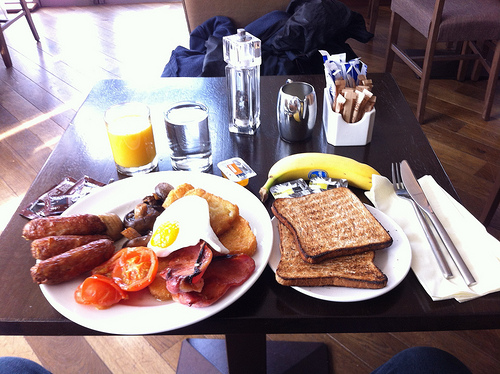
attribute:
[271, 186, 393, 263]
toast — a piece, brown, slice, plain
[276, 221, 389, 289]
toast — a piece, brown, slice, plain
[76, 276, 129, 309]
tomato — a piece, red, ripe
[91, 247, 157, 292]
tomato — a piece, red, ripe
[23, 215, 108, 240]
sausage — link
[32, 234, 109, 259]
sausage — link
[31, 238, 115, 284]
sausage — link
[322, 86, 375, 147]
container — white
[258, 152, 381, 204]
banana — yellow, ripe, unpeeled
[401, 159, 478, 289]
knife — silver, to eat with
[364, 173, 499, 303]
napkin — white, paper, folded in half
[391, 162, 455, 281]
fork — silver, to eat with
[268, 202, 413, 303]
plate — white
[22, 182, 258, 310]
foods — different, breakfast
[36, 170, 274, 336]
plate — white, full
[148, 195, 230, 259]
egg — cooked, fried, sunny side up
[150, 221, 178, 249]
yolk — yellow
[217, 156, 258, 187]
container — small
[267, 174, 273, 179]
spot — brown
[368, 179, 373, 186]
spot — brown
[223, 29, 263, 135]
grinder — clear, for salt, for pepper, glass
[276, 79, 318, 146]
pitcher — silver, for coffee creamer